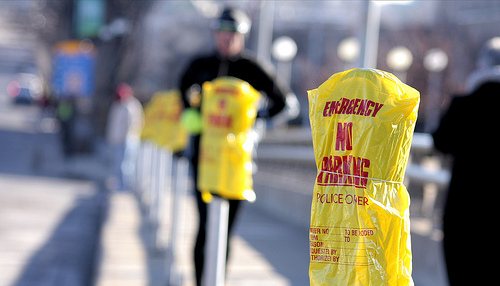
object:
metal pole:
[201, 198, 230, 286]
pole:
[151, 146, 174, 251]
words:
[317, 155, 371, 189]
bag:
[305, 67, 421, 286]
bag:
[143, 88, 189, 153]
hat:
[209, 7, 251, 34]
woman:
[176, 7, 287, 286]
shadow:
[19, 180, 110, 284]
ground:
[0, 131, 440, 284]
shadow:
[228, 200, 314, 283]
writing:
[364, 197, 369, 206]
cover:
[307, 67, 420, 286]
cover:
[197, 76, 261, 202]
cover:
[142, 90, 188, 154]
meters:
[137, 70, 419, 283]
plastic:
[306, 68, 421, 285]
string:
[318, 169, 405, 184]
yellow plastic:
[197, 76, 260, 203]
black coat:
[432, 76, 500, 286]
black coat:
[178, 52, 286, 159]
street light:
[386, 46, 413, 72]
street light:
[423, 48, 449, 73]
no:
[335, 122, 352, 151]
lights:
[335, 36, 361, 63]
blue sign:
[50, 52, 97, 98]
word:
[323, 97, 384, 117]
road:
[0, 133, 106, 286]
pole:
[166, 157, 191, 285]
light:
[269, 35, 297, 62]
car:
[7, 73, 44, 105]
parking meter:
[306, 67, 421, 286]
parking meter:
[196, 76, 261, 204]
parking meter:
[140, 89, 186, 152]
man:
[105, 82, 145, 189]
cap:
[116, 82, 134, 99]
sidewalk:
[106, 136, 498, 284]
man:
[176, 7, 288, 286]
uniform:
[176, 49, 284, 286]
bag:
[197, 76, 261, 203]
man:
[430, 69, 499, 286]